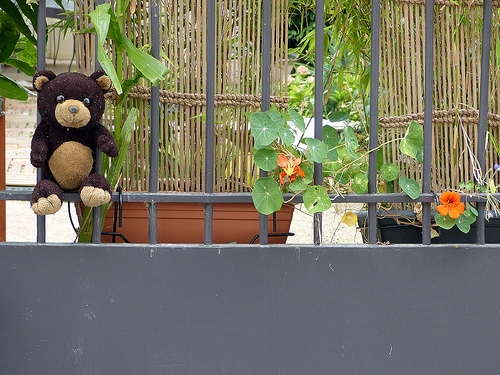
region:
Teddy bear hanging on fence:
[22, 72, 137, 242]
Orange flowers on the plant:
[271, 154, 461, 246]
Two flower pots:
[81, 175, 498, 235]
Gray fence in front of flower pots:
[3, 131, 469, 346]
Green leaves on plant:
[239, 72, 472, 231]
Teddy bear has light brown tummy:
[53, 129, 100, 208]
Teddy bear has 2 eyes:
[28, 65, 115, 152]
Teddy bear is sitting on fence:
[16, 130, 179, 253]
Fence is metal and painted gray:
[14, 97, 486, 357]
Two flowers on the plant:
[269, 130, 474, 236]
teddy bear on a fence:
[25, 66, 124, 212]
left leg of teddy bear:
[81, 169, 113, 204]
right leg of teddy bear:
[30, 172, 62, 217]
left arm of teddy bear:
[95, 122, 115, 152]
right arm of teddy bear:
[30, 121, 45, 164]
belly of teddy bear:
[52, 132, 92, 184]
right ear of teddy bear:
[30, 67, 56, 92]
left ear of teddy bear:
[91, 67, 112, 93]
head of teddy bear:
[32, 68, 122, 128]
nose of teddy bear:
[67, 103, 79, 113]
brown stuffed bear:
[20, 61, 122, 217]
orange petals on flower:
[270, 143, 313, 190]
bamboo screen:
[387, 5, 482, 225]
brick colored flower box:
[79, 169, 315, 246]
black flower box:
[354, 201, 498, 257]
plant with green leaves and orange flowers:
[228, 97, 430, 239]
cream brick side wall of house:
[2, 63, 31, 242]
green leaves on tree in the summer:
[290, 8, 365, 133]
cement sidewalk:
[296, 202, 374, 250]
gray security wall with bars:
[132, 3, 244, 369]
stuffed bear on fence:
[24, 62, 124, 229]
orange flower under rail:
[424, 189, 466, 226]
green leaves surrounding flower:
[244, 102, 338, 221]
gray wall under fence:
[128, 190, 245, 352]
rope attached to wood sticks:
[136, 83, 255, 116]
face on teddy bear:
[46, 91, 91, 133]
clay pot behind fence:
[116, 200, 250, 240]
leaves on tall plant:
[98, 26, 168, 113]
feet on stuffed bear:
[27, 182, 116, 221]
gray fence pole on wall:
[181, 35, 235, 257]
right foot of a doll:
[28, 182, 58, 215]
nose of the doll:
[68, 105, 80, 117]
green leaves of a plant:
[242, 100, 280, 217]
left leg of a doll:
[83, 172, 110, 216]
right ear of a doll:
[30, 66, 53, 79]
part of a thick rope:
[158, 81, 191, 108]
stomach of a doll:
[55, 147, 82, 188]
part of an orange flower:
[436, 181, 462, 228]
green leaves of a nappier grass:
[90, 10, 153, 99]